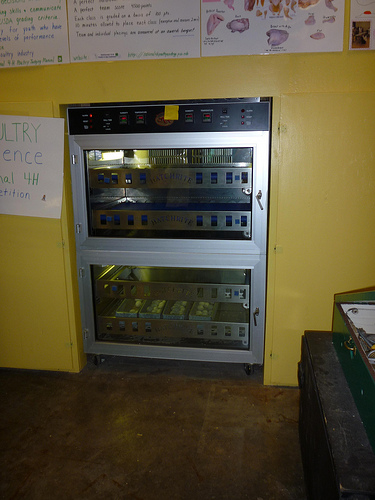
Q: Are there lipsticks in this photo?
A: No, there are no lipsticks.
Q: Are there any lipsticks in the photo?
A: No, there are no lipsticks.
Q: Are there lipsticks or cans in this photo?
A: No, there are no lipsticks or cans.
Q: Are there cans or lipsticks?
A: No, there are no lipsticks or cans.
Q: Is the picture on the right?
A: Yes, the picture is on the right of the image.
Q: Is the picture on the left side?
A: No, the picture is on the right of the image.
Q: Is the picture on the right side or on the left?
A: The picture is on the right of the image.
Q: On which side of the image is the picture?
A: The picture is on the right of the image.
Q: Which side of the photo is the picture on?
A: The picture is on the right of the image.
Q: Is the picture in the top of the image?
A: Yes, the picture is in the top of the image.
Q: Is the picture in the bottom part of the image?
A: No, the picture is in the top of the image.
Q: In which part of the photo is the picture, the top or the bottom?
A: The picture is in the top of the image.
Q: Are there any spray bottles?
A: No, there are no spray bottles.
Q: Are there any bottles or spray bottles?
A: No, there are no spray bottles or bottles.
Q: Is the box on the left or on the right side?
A: The box is on the right of the image.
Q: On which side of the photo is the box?
A: The box is on the right of the image.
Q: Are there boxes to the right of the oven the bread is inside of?
A: Yes, there is a box to the right of the oven.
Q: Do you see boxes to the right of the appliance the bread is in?
A: Yes, there is a box to the right of the oven.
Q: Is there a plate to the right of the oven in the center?
A: No, there is a box to the right of the oven.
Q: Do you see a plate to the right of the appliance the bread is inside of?
A: No, there is a box to the right of the oven.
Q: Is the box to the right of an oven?
A: Yes, the box is to the right of an oven.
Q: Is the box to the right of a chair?
A: No, the box is to the right of an oven.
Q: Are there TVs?
A: No, there are no tvs.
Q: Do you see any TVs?
A: No, there are no tvs.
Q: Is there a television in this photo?
A: No, there are no televisions.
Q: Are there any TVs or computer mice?
A: No, there are no TVs or computer mice.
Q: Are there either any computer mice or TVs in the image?
A: No, there are no TVs or computer mice.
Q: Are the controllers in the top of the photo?
A: Yes, the controllers are in the top of the image.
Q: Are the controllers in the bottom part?
A: No, the controllers are in the top of the image.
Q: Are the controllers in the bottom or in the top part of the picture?
A: The controllers are in the top of the image.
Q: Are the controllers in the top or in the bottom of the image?
A: The controllers are in the top of the image.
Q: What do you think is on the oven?
A: The controllers are on the oven.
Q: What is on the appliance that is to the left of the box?
A: The controllers are on the oven.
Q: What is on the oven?
A: The controllers are on the oven.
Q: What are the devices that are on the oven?
A: The devices are controllers.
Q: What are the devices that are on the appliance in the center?
A: The devices are controllers.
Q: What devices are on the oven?
A: The devices are controllers.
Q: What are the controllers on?
A: The controllers are on the oven.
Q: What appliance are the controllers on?
A: The controllers are on the oven.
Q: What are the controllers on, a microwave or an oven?
A: The controllers are on an oven.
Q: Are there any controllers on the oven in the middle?
A: Yes, there are controllers on the oven.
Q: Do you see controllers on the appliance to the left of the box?
A: Yes, there are controllers on the oven.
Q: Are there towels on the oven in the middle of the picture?
A: No, there are controllers on the oven.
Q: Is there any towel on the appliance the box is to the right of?
A: No, there are controllers on the oven.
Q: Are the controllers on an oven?
A: Yes, the controllers are on an oven.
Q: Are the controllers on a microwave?
A: No, the controllers are on an oven.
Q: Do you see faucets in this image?
A: No, there are no faucets.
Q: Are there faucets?
A: No, there are no faucets.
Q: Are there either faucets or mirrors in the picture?
A: No, there are no faucets or mirrors.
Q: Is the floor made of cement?
A: Yes, the floor is made of cement.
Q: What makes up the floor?
A: The floor is made of concrete.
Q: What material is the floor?
A: The floor is made of concrete.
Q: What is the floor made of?
A: The floor is made of concrete.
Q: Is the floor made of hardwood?
A: No, the floor is made of concrete.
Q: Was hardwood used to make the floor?
A: No, the floor is made of concrete.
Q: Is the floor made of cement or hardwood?
A: The floor is made of cement.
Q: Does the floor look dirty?
A: Yes, the floor is dirty.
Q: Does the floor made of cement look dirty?
A: Yes, the floor is dirty.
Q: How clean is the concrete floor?
A: The floor is dirty.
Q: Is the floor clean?
A: No, the floor is dirty.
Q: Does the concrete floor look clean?
A: No, the floor is dirty.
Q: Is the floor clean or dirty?
A: The floor is dirty.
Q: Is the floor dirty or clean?
A: The floor is dirty.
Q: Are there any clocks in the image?
A: No, there are no clocks.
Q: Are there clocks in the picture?
A: No, there are no clocks.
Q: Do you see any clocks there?
A: No, there are no clocks.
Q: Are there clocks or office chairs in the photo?
A: No, there are no clocks or office chairs.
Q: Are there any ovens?
A: Yes, there is an oven.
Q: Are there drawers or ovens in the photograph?
A: Yes, there is an oven.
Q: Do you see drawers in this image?
A: No, there are no drawers.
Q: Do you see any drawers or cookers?
A: No, there are no drawers or cookers.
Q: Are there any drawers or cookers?
A: No, there are no drawers or cookers.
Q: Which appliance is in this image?
A: The appliance is an oven.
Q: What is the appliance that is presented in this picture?
A: The appliance is an oven.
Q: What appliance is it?
A: The appliance is an oven.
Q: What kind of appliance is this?
A: That is an oven.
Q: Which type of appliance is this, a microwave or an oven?
A: That is an oven.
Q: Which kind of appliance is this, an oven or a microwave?
A: That is an oven.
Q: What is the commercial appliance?
A: The appliance is an oven.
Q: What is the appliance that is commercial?
A: The appliance is an oven.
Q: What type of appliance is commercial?
A: The appliance is an oven.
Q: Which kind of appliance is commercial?
A: The appliance is an oven.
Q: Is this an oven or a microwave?
A: This is an oven.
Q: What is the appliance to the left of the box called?
A: The appliance is an oven.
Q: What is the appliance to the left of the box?
A: The appliance is an oven.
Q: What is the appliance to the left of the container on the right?
A: The appliance is an oven.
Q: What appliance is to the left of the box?
A: The appliance is an oven.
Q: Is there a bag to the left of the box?
A: No, there is an oven to the left of the box.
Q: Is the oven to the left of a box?
A: Yes, the oven is to the left of a box.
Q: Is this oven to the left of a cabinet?
A: No, the oven is to the left of a box.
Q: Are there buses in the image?
A: No, there are no buses.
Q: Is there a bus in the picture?
A: No, there are no buses.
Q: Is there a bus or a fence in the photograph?
A: No, there are no buses or fences.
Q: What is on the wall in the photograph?
A: The sign is on the wall.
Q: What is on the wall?
A: The sign is on the wall.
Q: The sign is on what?
A: The sign is on the wall.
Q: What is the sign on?
A: The sign is on the wall.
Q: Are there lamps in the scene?
A: No, there are no lamps.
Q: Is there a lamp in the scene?
A: No, there are no lamps.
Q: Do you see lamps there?
A: No, there are no lamps.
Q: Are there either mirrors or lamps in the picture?
A: No, there are no lamps or mirrors.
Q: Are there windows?
A: Yes, there is a window.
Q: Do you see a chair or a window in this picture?
A: Yes, there is a window.